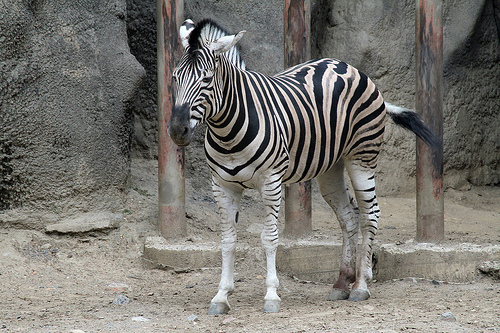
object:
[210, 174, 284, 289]
front legs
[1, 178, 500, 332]
ground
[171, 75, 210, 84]
zebra eyes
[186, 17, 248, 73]
zebra mane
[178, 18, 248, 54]
zebra ears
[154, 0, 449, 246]
wooden poles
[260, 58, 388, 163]
stripes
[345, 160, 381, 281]
zebra leg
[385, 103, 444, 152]
zebra tail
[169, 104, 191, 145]
black nose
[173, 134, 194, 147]
mouth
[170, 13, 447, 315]
zebra